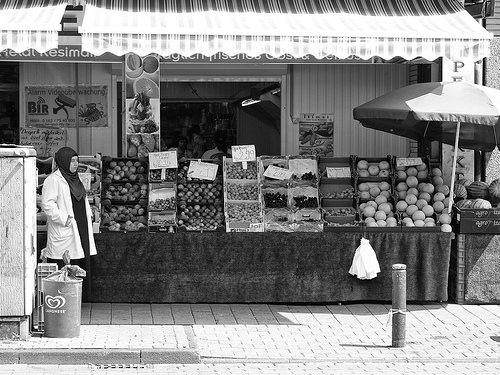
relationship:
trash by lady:
[40, 276, 83, 341] [42, 146, 96, 301]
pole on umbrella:
[447, 122, 461, 214] [351, 79, 499, 155]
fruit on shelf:
[288, 184, 319, 210] [95, 230, 452, 303]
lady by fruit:
[42, 146, 96, 301] [288, 184, 319, 210]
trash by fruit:
[40, 276, 83, 341] [288, 184, 319, 210]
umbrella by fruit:
[351, 79, 499, 155] [288, 184, 319, 210]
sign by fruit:
[22, 84, 108, 130] [288, 184, 319, 210]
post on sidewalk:
[391, 262, 407, 349] [3, 293, 499, 354]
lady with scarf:
[42, 146, 96, 301] [53, 145, 85, 202]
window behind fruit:
[159, 62, 283, 157] [288, 184, 319, 210]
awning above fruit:
[79, 1, 494, 64] [288, 184, 319, 210]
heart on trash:
[44, 294, 67, 310] [40, 276, 83, 341]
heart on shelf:
[44, 294, 67, 310] [95, 230, 452, 303]